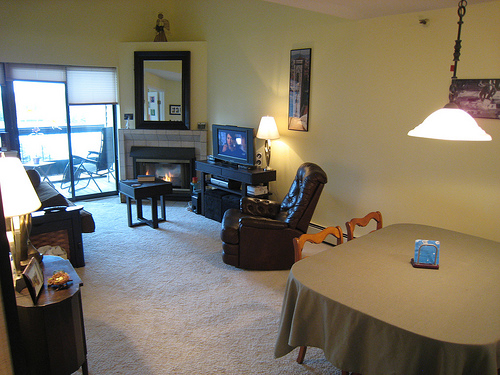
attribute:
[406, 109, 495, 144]
light — white, on, glass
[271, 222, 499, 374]
table — small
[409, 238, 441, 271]
napkin holder — blue, white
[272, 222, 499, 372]
cloth — brown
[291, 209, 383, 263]
chairs — wooden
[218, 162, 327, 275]
recliner — leather, brown, black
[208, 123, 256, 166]
television — on, black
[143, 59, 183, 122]
mirror — large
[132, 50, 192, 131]
frame — black, brown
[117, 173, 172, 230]
table — small, black, wooden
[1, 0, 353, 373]
living room — small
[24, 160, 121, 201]
deck — sunny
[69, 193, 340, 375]
carpet — tan, gray, white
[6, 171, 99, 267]
sofa — brown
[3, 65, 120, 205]
door — glass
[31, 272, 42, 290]
picture — small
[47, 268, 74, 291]
item — small, decorative